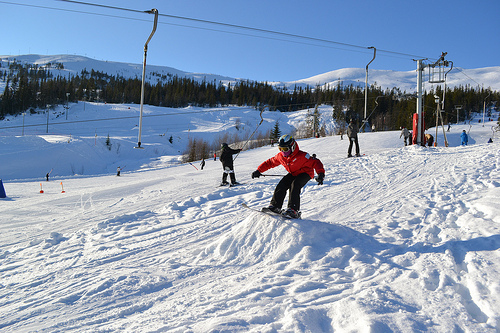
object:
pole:
[134, 7, 158, 148]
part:
[136, 8, 157, 148]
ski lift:
[1, 0, 446, 149]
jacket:
[219, 147, 240, 163]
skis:
[242, 203, 286, 215]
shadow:
[300, 219, 500, 271]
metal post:
[416, 59, 423, 146]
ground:
[419, 162, 431, 175]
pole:
[362, 46, 377, 122]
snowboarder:
[241, 134, 326, 219]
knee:
[274, 183, 288, 194]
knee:
[289, 184, 301, 196]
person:
[219, 142, 243, 187]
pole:
[233, 106, 268, 162]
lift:
[411, 52, 454, 83]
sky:
[0, 1, 497, 86]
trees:
[0, 57, 17, 119]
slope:
[95, 77, 358, 207]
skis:
[261, 207, 303, 219]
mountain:
[0, 53, 500, 179]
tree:
[461, 86, 466, 113]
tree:
[394, 96, 408, 123]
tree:
[483, 89, 498, 110]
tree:
[364, 82, 378, 132]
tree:
[320, 80, 332, 106]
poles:
[442, 60, 453, 81]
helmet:
[277, 134, 297, 153]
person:
[399, 126, 411, 147]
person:
[460, 130, 469, 147]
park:
[2, 122, 500, 333]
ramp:
[215, 211, 301, 263]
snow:
[0, 100, 500, 333]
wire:
[0, 0, 445, 67]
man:
[252, 134, 326, 219]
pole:
[416, 59, 423, 146]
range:
[0, 54, 497, 113]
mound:
[215, 211, 377, 268]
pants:
[269, 172, 312, 211]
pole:
[260, 174, 285, 177]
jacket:
[257, 150, 325, 179]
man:
[347, 118, 360, 157]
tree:
[50, 67, 58, 107]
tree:
[100, 74, 109, 103]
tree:
[157, 81, 178, 108]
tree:
[200, 77, 211, 106]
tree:
[236, 81, 242, 108]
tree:
[256, 80, 273, 108]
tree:
[40, 59, 66, 70]